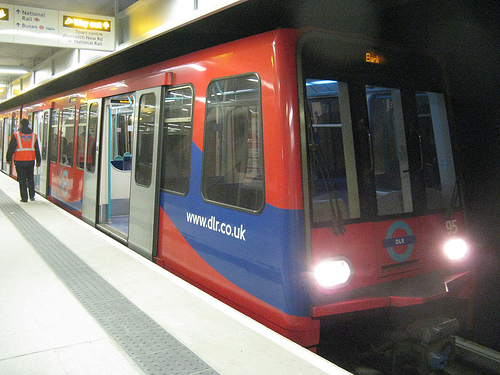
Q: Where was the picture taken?
A: In the train station.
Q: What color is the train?
A: Red and blue.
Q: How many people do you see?
A: 1 person.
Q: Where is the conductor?
A: On his way.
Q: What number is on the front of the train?
A: The number is 95.